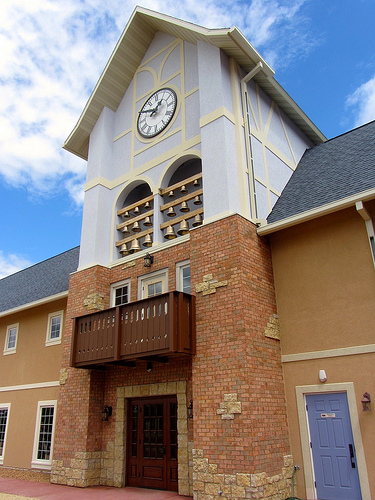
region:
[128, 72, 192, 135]
clock on the building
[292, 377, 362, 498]
door on the building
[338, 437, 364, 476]
handle of the door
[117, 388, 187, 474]
door at the bottom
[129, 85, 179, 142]
white clock with black numbers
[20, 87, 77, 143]
clouds in the sky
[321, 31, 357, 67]
blue sky above building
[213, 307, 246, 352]
bricks on the wall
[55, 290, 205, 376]
balcony on the building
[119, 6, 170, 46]
top of the building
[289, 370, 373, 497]
blue door with light on top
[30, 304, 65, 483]
two windows on the side of house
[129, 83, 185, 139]
clock on the house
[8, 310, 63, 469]
three windows on side of house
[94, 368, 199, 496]
door in brick wall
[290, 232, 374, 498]
blue door on side of house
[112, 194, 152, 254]
nine bells in a row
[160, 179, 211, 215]
six bells in a row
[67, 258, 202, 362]
three windows behind belcony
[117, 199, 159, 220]
three bells in a row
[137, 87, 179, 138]
The clock on the building.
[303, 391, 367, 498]
The purple door on the right side.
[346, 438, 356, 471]
The black door knob on the purple door.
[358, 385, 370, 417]
The light to the right of the purple door.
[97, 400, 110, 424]
The light on the left of the burgundy door.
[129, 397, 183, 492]
The main door of the building.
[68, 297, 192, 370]
The brown balcony of the building.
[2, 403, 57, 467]
The bottom windows on the left.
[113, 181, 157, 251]
The golden bells on the left.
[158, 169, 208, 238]
The golden bells on the right.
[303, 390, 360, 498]
Purple door on building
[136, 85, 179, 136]
Round black and white clock on building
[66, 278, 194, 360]
Brown balcony on building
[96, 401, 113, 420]
Black lamp next to red door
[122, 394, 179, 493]
Door is red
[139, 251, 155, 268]
Black lamp above balcony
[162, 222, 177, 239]
Gold bell above balcony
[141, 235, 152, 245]
Gold bell above balcony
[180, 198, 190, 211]
Gold bell next to gold bell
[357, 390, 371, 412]
Small lamp next to blue door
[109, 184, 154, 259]
set of gold bells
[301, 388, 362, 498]
blue door on building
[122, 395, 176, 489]
brown door with windows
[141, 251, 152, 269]
black light in building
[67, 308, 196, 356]
brown deck below windows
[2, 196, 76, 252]
clear sunny blue sky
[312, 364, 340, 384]
white light above door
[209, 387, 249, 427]
tan bricks on building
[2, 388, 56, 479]
two windows on building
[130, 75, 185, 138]
black and white clock